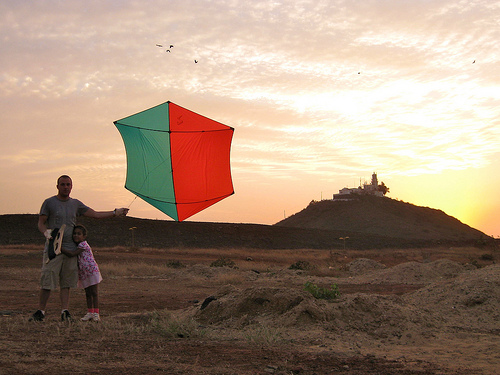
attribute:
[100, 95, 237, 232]
kite — large, green, red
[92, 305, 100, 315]
sock — pink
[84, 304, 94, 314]
sock — pink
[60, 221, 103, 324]
girl — little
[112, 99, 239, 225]
kite — red and green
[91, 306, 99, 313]
sock — pink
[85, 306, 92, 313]
sock — pink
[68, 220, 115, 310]
girl — little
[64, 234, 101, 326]
girl — little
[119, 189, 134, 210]
string — green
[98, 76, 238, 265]
kite — red and green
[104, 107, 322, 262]
kite — green and yellow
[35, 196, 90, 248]
shirt — gray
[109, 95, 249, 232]
kite — red